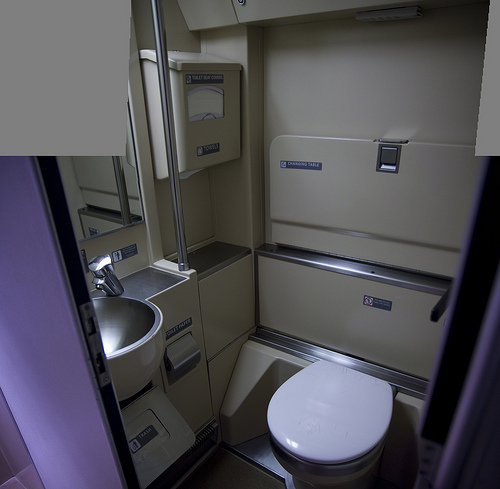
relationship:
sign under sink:
[126, 422, 157, 453] [75, 243, 201, 390]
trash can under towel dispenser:
[175, 235, 270, 347] [134, 48, 239, 178]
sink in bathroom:
[90, 295, 167, 402] [6, 9, 483, 478]